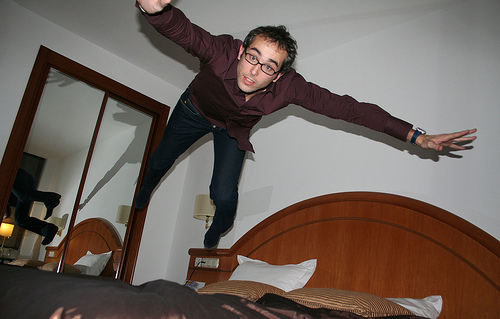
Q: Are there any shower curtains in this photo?
A: No, there are no shower curtains.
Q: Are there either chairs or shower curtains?
A: No, there are no shower curtains or chairs.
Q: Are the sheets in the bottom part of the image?
A: Yes, the sheets are in the bottom of the image.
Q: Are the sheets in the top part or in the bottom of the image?
A: The sheets are in the bottom of the image.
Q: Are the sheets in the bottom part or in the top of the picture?
A: The sheets are in the bottom of the image.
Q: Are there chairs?
A: No, there are no chairs.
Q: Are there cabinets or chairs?
A: No, there are no chairs or cabinets.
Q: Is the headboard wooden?
A: Yes, the headboard is wooden.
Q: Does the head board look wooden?
A: Yes, the head board is wooden.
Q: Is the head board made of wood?
A: Yes, the head board is made of wood.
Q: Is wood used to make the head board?
A: Yes, the head board is made of wood.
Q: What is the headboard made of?
A: The headboard is made of wood.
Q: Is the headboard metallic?
A: No, the headboard is wooden.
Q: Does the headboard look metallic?
A: No, the headboard is wooden.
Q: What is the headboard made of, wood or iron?
A: The headboard is made of wood.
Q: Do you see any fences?
A: No, there are no fences.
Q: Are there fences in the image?
A: No, there are no fences.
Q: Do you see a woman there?
A: No, there are no women.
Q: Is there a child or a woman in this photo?
A: No, there are no women or children.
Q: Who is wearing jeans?
A: The man is wearing jeans.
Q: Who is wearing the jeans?
A: The man is wearing jeans.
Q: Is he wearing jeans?
A: Yes, the man is wearing jeans.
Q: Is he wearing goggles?
A: No, the man is wearing jeans.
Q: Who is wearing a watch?
A: The man is wearing a watch.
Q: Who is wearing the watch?
A: The man is wearing a watch.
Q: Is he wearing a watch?
A: Yes, the man is wearing a watch.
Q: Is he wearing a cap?
A: No, the man is wearing a watch.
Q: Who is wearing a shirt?
A: The man is wearing a shirt.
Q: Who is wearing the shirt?
A: The man is wearing a shirt.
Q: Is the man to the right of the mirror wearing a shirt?
A: Yes, the man is wearing a shirt.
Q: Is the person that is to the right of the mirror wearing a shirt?
A: Yes, the man is wearing a shirt.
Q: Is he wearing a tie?
A: No, the man is wearing a shirt.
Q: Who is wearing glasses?
A: The man is wearing glasses.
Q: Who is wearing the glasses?
A: The man is wearing glasses.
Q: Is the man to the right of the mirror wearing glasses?
A: Yes, the man is wearing glasses.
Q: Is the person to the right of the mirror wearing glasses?
A: Yes, the man is wearing glasses.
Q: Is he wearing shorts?
A: No, the man is wearing glasses.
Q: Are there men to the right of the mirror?
A: Yes, there is a man to the right of the mirror.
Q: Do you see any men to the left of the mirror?
A: No, the man is to the right of the mirror.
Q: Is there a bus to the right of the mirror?
A: No, there is a man to the right of the mirror.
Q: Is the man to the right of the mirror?
A: Yes, the man is to the right of the mirror.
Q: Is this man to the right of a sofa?
A: No, the man is to the right of the mirror.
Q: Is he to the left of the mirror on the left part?
A: No, the man is to the right of the mirror.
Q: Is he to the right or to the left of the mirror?
A: The man is to the right of the mirror.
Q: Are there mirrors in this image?
A: Yes, there is a mirror.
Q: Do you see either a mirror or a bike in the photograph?
A: Yes, there is a mirror.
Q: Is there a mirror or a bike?
A: Yes, there is a mirror.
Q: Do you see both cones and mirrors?
A: No, there is a mirror but no cones.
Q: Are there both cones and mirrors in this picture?
A: No, there is a mirror but no cones.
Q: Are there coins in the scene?
A: No, there are no coins.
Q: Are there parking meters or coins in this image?
A: No, there are no coins or parking meters.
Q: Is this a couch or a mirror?
A: This is a mirror.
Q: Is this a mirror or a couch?
A: This is a mirror.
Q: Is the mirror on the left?
A: Yes, the mirror is on the left of the image.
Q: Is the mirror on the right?
A: No, the mirror is on the left of the image.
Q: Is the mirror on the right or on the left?
A: The mirror is on the left of the image.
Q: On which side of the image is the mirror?
A: The mirror is on the left of the image.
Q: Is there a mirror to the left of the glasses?
A: Yes, there is a mirror to the left of the glasses.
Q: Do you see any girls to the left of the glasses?
A: No, there is a mirror to the left of the glasses.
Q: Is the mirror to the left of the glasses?
A: Yes, the mirror is to the left of the glasses.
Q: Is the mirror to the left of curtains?
A: No, the mirror is to the left of the glasses.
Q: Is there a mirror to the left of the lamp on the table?
A: Yes, there is a mirror to the left of the lamp.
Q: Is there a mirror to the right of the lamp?
A: No, the mirror is to the left of the lamp.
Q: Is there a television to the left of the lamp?
A: No, there is a mirror to the left of the lamp.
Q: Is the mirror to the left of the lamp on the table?
A: Yes, the mirror is to the left of the lamp.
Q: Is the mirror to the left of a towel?
A: No, the mirror is to the left of the lamp.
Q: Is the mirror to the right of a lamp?
A: No, the mirror is to the left of a lamp.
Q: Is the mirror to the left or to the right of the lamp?
A: The mirror is to the left of the lamp.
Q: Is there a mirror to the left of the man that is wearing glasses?
A: Yes, there is a mirror to the left of the man.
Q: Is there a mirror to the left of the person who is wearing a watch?
A: Yes, there is a mirror to the left of the man.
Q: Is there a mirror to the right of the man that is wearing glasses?
A: No, the mirror is to the left of the man.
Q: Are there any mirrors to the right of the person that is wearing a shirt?
A: No, the mirror is to the left of the man.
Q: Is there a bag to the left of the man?
A: No, there is a mirror to the left of the man.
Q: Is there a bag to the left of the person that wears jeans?
A: No, there is a mirror to the left of the man.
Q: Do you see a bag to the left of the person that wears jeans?
A: No, there is a mirror to the left of the man.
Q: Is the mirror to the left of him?
A: Yes, the mirror is to the left of a man.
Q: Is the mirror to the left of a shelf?
A: No, the mirror is to the left of a man.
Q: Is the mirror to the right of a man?
A: No, the mirror is to the left of a man.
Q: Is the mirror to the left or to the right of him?
A: The mirror is to the left of the man.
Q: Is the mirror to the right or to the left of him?
A: The mirror is to the left of the man.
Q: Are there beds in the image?
A: Yes, there is a bed.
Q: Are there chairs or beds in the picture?
A: Yes, there is a bed.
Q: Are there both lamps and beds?
A: Yes, there are both a bed and a lamp.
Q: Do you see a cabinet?
A: No, there are no cabinets.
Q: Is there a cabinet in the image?
A: No, there are no cabinets.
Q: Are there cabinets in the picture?
A: No, there are no cabinets.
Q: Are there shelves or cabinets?
A: No, there are no cabinets or shelves.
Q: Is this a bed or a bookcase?
A: This is a bed.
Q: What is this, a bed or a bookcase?
A: This is a bed.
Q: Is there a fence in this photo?
A: No, there are no fences.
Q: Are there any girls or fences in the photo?
A: No, there are no fences or girls.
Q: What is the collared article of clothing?
A: The clothing item is a shirt.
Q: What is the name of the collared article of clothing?
A: The clothing item is a shirt.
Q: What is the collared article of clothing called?
A: The clothing item is a shirt.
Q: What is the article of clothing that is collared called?
A: The clothing item is a shirt.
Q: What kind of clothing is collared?
A: The clothing is a shirt.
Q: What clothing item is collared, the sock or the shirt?
A: The shirt is collared.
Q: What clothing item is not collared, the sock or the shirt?
A: The sock is not collared.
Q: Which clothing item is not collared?
A: The clothing item is a sock.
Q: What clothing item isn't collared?
A: The clothing item is a sock.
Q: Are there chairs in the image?
A: No, there are no chairs.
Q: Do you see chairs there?
A: No, there are no chairs.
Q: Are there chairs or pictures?
A: No, there are no chairs or pictures.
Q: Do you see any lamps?
A: Yes, there is a lamp.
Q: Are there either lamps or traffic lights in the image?
A: Yes, there is a lamp.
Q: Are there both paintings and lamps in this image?
A: No, there is a lamp but no paintings.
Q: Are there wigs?
A: No, there are no wigs.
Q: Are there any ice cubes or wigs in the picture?
A: No, there are no wigs or ice cubes.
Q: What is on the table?
A: The lamp is on the table.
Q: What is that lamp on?
A: The lamp is on the table.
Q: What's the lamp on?
A: The lamp is on the table.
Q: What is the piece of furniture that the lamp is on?
A: The piece of furniture is a table.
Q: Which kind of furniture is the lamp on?
A: The lamp is on the table.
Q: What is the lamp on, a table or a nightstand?
A: The lamp is on a table.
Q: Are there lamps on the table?
A: Yes, there is a lamp on the table.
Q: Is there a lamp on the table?
A: Yes, there is a lamp on the table.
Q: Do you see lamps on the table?
A: Yes, there is a lamp on the table.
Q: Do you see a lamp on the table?
A: Yes, there is a lamp on the table.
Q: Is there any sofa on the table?
A: No, there is a lamp on the table.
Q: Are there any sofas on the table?
A: No, there is a lamp on the table.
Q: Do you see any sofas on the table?
A: No, there is a lamp on the table.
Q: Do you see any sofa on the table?
A: No, there is a lamp on the table.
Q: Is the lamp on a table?
A: Yes, the lamp is on a table.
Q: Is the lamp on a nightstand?
A: No, the lamp is on a table.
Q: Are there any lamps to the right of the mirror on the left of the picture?
A: Yes, there is a lamp to the right of the mirror.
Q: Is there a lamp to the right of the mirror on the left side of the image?
A: Yes, there is a lamp to the right of the mirror.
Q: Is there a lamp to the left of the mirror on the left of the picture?
A: No, the lamp is to the right of the mirror.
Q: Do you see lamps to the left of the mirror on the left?
A: No, the lamp is to the right of the mirror.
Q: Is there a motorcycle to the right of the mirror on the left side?
A: No, there is a lamp to the right of the mirror.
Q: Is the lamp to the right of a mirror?
A: Yes, the lamp is to the right of a mirror.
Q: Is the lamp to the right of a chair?
A: No, the lamp is to the right of a mirror.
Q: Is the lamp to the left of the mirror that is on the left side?
A: No, the lamp is to the right of the mirror.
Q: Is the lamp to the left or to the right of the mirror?
A: The lamp is to the right of the mirror.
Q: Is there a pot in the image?
A: No, there are no pots.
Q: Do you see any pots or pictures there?
A: No, there are no pots or pictures.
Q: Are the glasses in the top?
A: Yes, the glasses are in the top of the image.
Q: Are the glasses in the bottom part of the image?
A: No, the glasses are in the top of the image.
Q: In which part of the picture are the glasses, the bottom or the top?
A: The glasses are in the top of the image.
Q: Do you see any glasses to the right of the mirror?
A: Yes, there are glasses to the right of the mirror.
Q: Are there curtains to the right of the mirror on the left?
A: No, there are glasses to the right of the mirror.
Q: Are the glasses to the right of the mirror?
A: Yes, the glasses are to the right of the mirror.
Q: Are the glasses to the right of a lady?
A: No, the glasses are to the right of the mirror.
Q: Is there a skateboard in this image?
A: No, there are no skateboards.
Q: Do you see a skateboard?
A: No, there are no skateboards.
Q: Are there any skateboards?
A: No, there are no skateboards.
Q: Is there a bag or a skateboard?
A: No, there are no skateboards or bags.